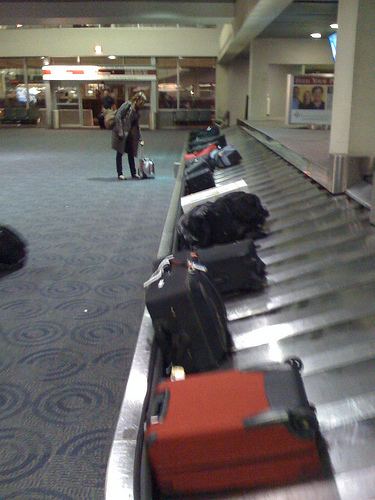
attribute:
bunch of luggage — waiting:
[179, 152, 264, 292]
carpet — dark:
[62, 204, 133, 255]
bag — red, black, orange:
[146, 356, 333, 485]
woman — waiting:
[112, 87, 159, 189]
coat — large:
[120, 102, 143, 151]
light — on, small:
[312, 30, 328, 43]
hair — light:
[136, 93, 146, 107]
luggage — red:
[185, 139, 219, 159]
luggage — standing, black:
[153, 256, 232, 374]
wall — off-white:
[127, 31, 217, 58]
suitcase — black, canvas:
[196, 238, 271, 288]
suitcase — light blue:
[211, 146, 243, 168]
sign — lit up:
[162, 81, 182, 93]